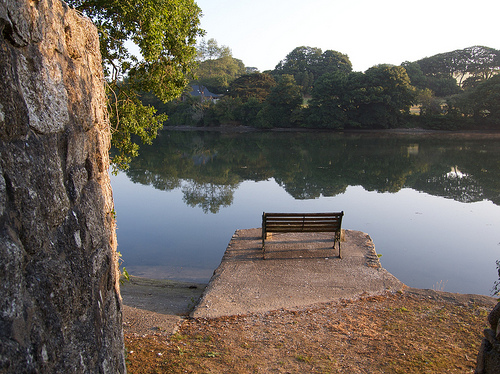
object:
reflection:
[110, 130, 499, 214]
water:
[162, 143, 254, 201]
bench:
[262, 211, 345, 259]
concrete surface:
[189, 228, 405, 319]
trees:
[352, 63, 431, 113]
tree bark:
[0, 0, 128, 374]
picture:
[0, 1, 498, 374]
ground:
[118, 286, 500, 374]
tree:
[0, 0, 207, 374]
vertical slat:
[301, 215, 305, 233]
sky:
[104, 0, 500, 74]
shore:
[162, 127, 499, 133]